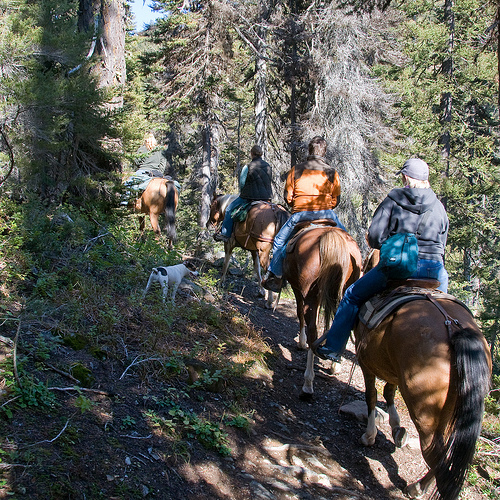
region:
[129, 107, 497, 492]
people riding horses on a path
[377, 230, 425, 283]
blue bag of a horse rider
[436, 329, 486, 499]
tail of a brown horse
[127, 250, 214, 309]
dog walking along side of path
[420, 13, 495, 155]
green trees in the woods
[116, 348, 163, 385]
wooden tree branch on the floor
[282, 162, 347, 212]
orange jacket of a horse rider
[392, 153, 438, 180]
grey baseball cap of a person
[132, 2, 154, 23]
blue sky in the distance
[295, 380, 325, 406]
back hoof of a horse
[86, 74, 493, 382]
horses in the forest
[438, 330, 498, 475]
black tail of horse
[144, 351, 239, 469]
green grass on ground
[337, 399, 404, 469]
white hooves of horse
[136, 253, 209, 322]
dog next to horses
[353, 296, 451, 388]
brown horse being ridden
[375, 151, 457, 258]
person wearing a hat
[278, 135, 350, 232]
person in orange clothing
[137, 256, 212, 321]
dog with spot on back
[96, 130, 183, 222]
horse with person riding it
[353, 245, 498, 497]
a brown horse with a dark tail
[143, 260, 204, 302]
a dog looking at all of the horses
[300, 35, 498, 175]
some trees on the side of the trail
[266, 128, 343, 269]
a person riding a horse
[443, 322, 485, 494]
the long black tail of the last horse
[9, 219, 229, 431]
some plants on the ground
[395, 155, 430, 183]
the hat on the woman's head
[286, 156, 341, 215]
the orange and black jacket on the man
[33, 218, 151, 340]
some more of the plants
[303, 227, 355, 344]
the light brown tail of the dog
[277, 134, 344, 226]
Man in orange and black jacket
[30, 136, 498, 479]
Four people riding horses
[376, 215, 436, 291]
Green backpack on woman in gray's side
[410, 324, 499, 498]
Black tail on closest horse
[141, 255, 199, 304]
White dog with black spots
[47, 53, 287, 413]
Heavily wooded outdoor area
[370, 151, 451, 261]
Woman wearing gray hat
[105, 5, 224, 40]
Blue sky peeking through trees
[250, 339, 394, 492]
Shadow of horse on ground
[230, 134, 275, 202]
Man wearing black vest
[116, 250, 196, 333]
Small dog in woods.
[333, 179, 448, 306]
Person carrying a blue pack.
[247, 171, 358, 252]
Person wearing orange jacket.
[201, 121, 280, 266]
Person wearing a vest.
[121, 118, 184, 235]
Person wearing a green jacket.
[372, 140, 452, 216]
Person in a hat.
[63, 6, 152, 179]
Large Brown tree trunk.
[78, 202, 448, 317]
Dog beside some horses.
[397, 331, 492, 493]
Tail of a horse.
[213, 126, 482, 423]
Three people riding horses.